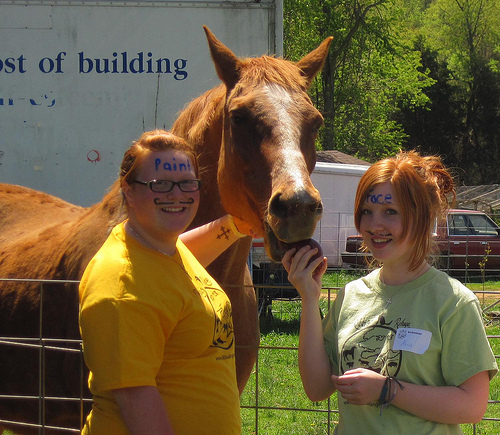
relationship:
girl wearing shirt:
[286, 145, 498, 434] [326, 256, 498, 430]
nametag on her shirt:
[393, 327, 433, 354] [326, 256, 498, 430]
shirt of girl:
[326, 256, 498, 430] [286, 145, 498, 434]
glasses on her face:
[135, 171, 202, 198] [141, 147, 206, 241]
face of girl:
[141, 147, 206, 241] [77, 134, 251, 434]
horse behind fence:
[4, 24, 333, 429] [6, 276, 480, 434]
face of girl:
[141, 147, 198, 230] [77, 134, 251, 434]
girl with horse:
[280, 145, 497, 435] [4, 24, 333, 429]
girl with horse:
[74, 127, 247, 435] [4, 24, 333, 429]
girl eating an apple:
[280, 145, 497, 435] [288, 234, 328, 283]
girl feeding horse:
[280, 145, 497, 435] [4, 24, 333, 429]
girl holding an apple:
[280, 145, 497, 435] [288, 244, 329, 282]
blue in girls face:
[367, 189, 392, 204] [360, 184, 419, 284]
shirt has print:
[76, 240, 252, 432] [200, 297, 234, 360]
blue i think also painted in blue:
[367, 189, 392, 204] [364, 189, 394, 205]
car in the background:
[341, 204, 484, 273] [326, 57, 485, 257]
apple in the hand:
[292, 235, 325, 274] [280, 244, 330, 300]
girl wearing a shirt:
[74, 123, 248, 421] [73, 222, 241, 424]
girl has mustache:
[74, 127, 247, 435] [155, 194, 193, 212]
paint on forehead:
[152, 146, 195, 173] [135, 150, 195, 184]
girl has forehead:
[74, 127, 247, 435] [135, 150, 195, 184]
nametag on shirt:
[393, 327, 433, 354] [326, 256, 498, 430]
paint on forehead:
[155, 158, 191, 172] [141, 146, 197, 187]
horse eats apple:
[4, 24, 333, 429] [284, 230, 325, 277]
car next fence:
[340, 209, 500, 275] [441, 230, 499, 288]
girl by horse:
[74, 127, 247, 435] [4, 24, 333, 429]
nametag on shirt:
[386, 317, 436, 357] [326, 256, 498, 430]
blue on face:
[367, 189, 392, 204] [352, 177, 410, 269]